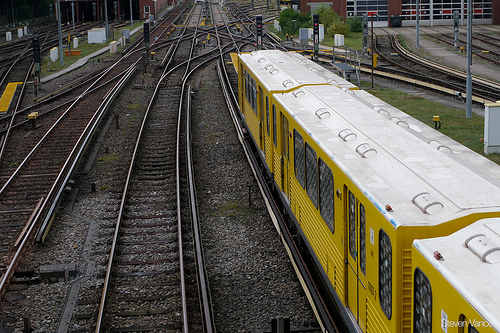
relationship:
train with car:
[234, 44, 495, 331] [237, 35, 343, 157]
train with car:
[234, 44, 495, 331] [267, 84, 498, 329]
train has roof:
[234, 44, 495, 331] [235, 46, 498, 326]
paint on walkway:
[1, 81, 23, 109] [0, 82, 27, 114]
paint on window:
[320, 169, 331, 229] [318, 157, 337, 234]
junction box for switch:
[144, 20, 148, 40] [156, 43, 160, 55]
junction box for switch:
[31, 34, 44, 56] [31, 74, 42, 100]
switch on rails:
[156, 43, 160, 55] [7, 8, 494, 325]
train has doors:
[234, 44, 495, 331] [345, 187, 368, 319]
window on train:
[318, 157, 337, 234] [234, 44, 495, 331]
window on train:
[318, 157, 337, 229] [234, 44, 495, 331]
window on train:
[291, 134, 305, 184] [234, 44, 495, 331]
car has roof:
[237, 35, 343, 157] [235, 46, 498, 326]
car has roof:
[267, 84, 498, 329] [235, 46, 498, 326]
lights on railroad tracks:
[256, 16, 264, 34] [94, 0, 205, 332]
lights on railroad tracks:
[312, 14, 322, 34] [94, 0, 205, 332]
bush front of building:
[323, 22, 352, 36] [294, 0, 499, 32]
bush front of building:
[276, 7, 305, 34] [294, 0, 499, 32]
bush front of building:
[342, 11, 367, 30] [294, 0, 499, 32]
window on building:
[349, 8, 355, 13] [294, 0, 499, 32]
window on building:
[367, 2, 379, 8] [294, 0, 499, 32]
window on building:
[359, 10, 370, 15] [294, 0, 499, 32]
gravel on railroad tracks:
[9, 5, 226, 317] [94, 0, 205, 332]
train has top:
[234, 44, 495, 331] [239, 45, 495, 324]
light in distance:
[254, 22, 262, 28] [5, 0, 500, 122]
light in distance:
[313, 22, 317, 27] [5, 0, 500, 122]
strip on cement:
[3, 81, 23, 108] [1, 81, 26, 114]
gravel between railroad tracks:
[9, 5, 226, 317] [94, 0, 205, 332]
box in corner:
[483, 104, 500, 155] [303, 68, 499, 325]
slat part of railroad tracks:
[297, 52, 499, 108] [94, 0, 205, 332]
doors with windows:
[345, 187, 368, 319] [345, 188, 373, 270]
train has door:
[234, 44, 495, 331] [345, 187, 368, 319]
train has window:
[234, 44, 495, 331] [291, 134, 305, 184]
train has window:
[234, 44, 495, 331] [318, 157, 337, 234]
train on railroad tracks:
[234, 44, 495, 331] [94, 0, 205, 332]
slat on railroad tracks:
[297, 54, 494, 105] [94, 0, 205, 332]